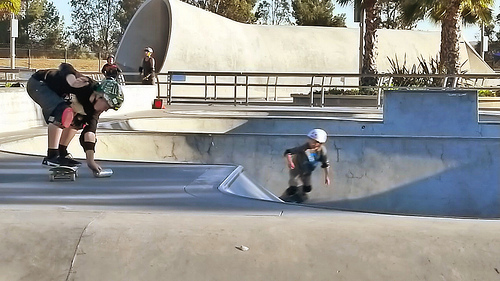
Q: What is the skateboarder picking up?
A: Soda.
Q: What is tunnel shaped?
A: The building.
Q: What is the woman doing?
A: Bending.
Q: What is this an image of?
A: A skate park.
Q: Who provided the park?
A: Community.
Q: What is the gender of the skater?
A: Female.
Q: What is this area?
A: Half pipe.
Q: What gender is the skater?
A: Male.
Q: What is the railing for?
A: Safety.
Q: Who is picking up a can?
A: A teenager.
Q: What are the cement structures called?
A: A skatepark.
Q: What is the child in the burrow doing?
A: Skating.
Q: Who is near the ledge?
A: A child bending.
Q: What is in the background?
A: Trees.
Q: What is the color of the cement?
A: Light grey.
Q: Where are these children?
A: At a skatepark.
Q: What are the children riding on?
A: Skateboards.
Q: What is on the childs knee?
A: A red kneepad.